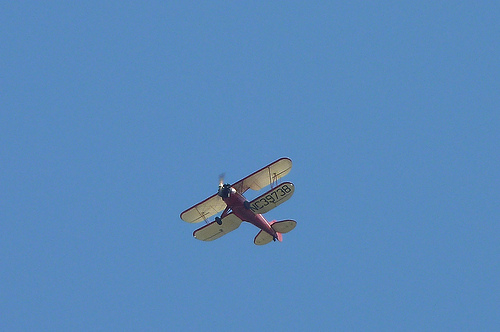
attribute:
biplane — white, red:
[181, 157, 297, 246]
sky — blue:
[0, 1, 456, 154]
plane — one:
[166, 145, 302, 250]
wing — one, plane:
[253, 180, 302, 212]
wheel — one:
[208, 210, 228, 230]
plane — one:
[185, 150, 312, 266]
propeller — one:
[211, 163, 232, 193]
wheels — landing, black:
[209, 188, 274, 229]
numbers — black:
[253, 183, 298, 214]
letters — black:
[252, 182, 296, 212]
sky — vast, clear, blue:
[129, 51, 217, 127]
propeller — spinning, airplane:
[217, 172, 234, 192]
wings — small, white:
[255, 218, 298, 243]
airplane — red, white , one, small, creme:
[178, 150, 298, 254]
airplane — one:
[188, 148, 309, 243]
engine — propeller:
[215, 175, 235, 195]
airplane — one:
[189, 158, 301, 248]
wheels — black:
[214, 189, 257, 226]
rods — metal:
[204, 164, 287, 225]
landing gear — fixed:
[210, 195, 253, 228]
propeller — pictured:
[212, 168, 227, 198]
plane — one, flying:
[177, 151, 303, 250]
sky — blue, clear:
[3, 6, 499, 326]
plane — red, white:
[179, 148, 299, 257]